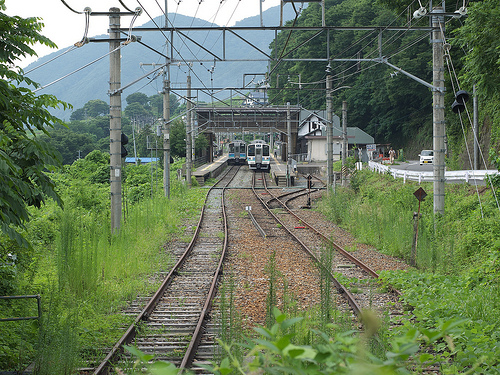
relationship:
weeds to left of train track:
[316, 236, 332, 321] [249, 167, 460, 373]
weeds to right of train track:
[218, 265, 237, 340] [90, 163, 241, 374]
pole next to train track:
[109, 7, 124, 236] [90, 163, 241, 374]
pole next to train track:
[162, 80, 174, 200] [90, 163, 241, 374]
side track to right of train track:
[267, 171, 322, 209] [249, 167, 460, 373]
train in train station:
[246, 140, 272, 169] [189, 102, 375, 189]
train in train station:
[225, 139, 249, 166] [189, 102, 375, 189]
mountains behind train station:
[9, 2, 311, 136] [189, 102, 375, 189]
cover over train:
[189, 106, 300, 133] [246, 140, 272, 169]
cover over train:
[189, 106, 300, 133] [225, 139, 249, 166]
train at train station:
[225, 139, 249, 166] [189, 102, 375, 189]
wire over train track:
[159, 1, 183, 64] [90, 163, 241, 374]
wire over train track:
[172, 1, 202, 62] [90, 163, 241, 374]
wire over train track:
[192, 1, 224, 60] [90, 163, 241, 374]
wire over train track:
[200, 1, 241, 61] [90, 163, 241, 374]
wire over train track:
[291, 31, 433, 85] [249, 167, 460, 373]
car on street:
[419, 149, 435, 166] [385, 159, 491, 174]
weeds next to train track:
[325, 165, 499, 373] [249, 167, 460, 373]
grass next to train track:
[80, 192, 186, 297] [90, 163, 241, 374]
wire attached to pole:
[10, 7, 143, 97] [109, 7, 124, 236]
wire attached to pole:
[9, 7, 91, 88] [109, 7, 124, 236]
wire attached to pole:
[291, 31, 433, 85] [429, 7, 449, 218]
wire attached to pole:
[438, 25, 499, 226] [429, 7, 449, 218]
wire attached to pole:
[172, 1, 202, 62] [162, 80, 174, 200]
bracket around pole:
[109, 89, 125, 96] [109, 7, 124, 236]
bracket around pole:
[109, 105, 123, 110] [109, 7, 124, 236]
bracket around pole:
[111, 126, 122, 133] [109, 7, 124, 236]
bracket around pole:
[110, 151, 124, 160] [109, 7, 124, 236]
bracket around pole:
[110, 179, 121, 184] [109, 7, 124, 236]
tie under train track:
[121, 311, 200, 319] [90, 163, 241, 374]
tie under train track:
[127, 345, 218, 352] [90, 163, 241, 374]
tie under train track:
[160, 295, 208, 299] [90, 163, 241, 374]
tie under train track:
[153, 309, 201, 314] [90, 163, 241, 374]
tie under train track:
[130, 345, 187, 350] [90, 163, 241, 374]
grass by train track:
[80, 192, 186, 297] [90, 163, 241, 374]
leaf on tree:
[67, 103, 74, 109] [1, 0, 74, 295]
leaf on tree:
[25, 76, 32, 86] [1, 0, 74, 295]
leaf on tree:
[21, 51, 27, 58] [1, 0, 74, 295]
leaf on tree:
[32, 187, 40, 198] [1, 0, 74, 295]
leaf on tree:
[21, 207, 31, 223] [1, 0, 74, 295]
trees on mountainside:
[267, 1, 434, 146] [267, 0, 433, 161]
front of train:
[245, 145, 269, 167] [246, 140, 272, 169]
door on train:
[254, 148, 262, 165] [246, 140, 272, 169]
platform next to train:
[269, 151, 294, 178] [246, 140, 272, 169]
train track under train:
[249, 167, 460, 373] [246, 140, 272, 169]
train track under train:
[90, 163, 241, 374] [225, 139, 249, 166]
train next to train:
[246, 140, 272, 169] [225, 139, 249, 166]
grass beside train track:
[80, 192, 186, 297] [90, 163, 241, 374]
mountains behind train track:
[9, 2, 311, 136] [249, 167, 460, 373]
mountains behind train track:
[9, 2, 311, 136] [90, 163, 241, 374]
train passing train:
[246, 140, 272, 169] [225, 139, 249, 166]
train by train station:
[246, 140, 272, 169] [189, 102, 375, 189]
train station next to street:
[189, 102, 375, 189] [385, 159, 491, 174]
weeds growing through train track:
[338, 271, 380, 294] [249, 167, 460, 373]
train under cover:
[246, 140, 272, 169] [189, 106, 300, 133]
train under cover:
[225, 139, 249, 166] [189, 106, 300, 133]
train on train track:
[246, 140, 272, 169] [249, 167, 460, 373]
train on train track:
[225, 139, 249, 166] [90, 163, 241, 374]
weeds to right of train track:
[325, 165, 499, 373] [249, 167, 460, 373]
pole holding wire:
[109, 7, 124, 236] [10, 7, 143, 97]